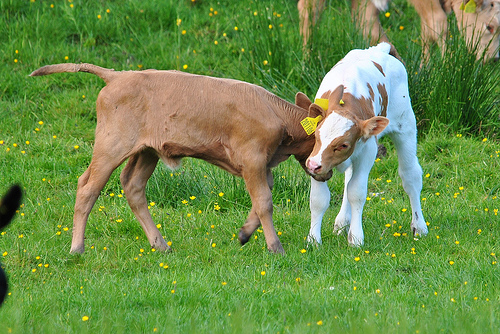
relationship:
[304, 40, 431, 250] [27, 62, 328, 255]
calf playing with brown cow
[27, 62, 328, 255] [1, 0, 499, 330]
brown cow in grass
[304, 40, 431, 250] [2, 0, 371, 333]
calf in grass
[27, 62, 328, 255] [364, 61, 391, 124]
brown cow with spots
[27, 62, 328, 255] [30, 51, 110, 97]
brown cow has tail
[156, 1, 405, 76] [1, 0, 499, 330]
flowers in grass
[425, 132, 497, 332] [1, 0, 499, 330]
flowers in grass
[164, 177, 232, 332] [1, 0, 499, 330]
flowers in grass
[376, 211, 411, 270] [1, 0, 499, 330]
flowers in grass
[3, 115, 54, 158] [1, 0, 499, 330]
flowers in grass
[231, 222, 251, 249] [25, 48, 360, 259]
hoof of cow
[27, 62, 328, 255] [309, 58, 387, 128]
brown cow has markings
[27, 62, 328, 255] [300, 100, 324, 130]
brown cow has ear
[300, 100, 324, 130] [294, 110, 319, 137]
ear has tag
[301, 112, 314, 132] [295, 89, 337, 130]
tag in calves ear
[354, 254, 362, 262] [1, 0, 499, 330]
dandelions in grass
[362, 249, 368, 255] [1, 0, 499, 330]
flower in grass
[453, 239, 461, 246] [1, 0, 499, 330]
flower in grass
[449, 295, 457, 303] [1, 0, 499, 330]
flower in grass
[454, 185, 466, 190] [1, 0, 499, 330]
flower in grass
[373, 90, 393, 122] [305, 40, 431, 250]
markings on calf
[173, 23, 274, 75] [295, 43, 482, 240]
grass behind cow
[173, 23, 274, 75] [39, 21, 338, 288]
grass behind calf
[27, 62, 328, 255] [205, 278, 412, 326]
brown cow eating grass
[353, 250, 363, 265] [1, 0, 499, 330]
dandelions on grass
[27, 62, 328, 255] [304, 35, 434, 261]
brown cow near cow